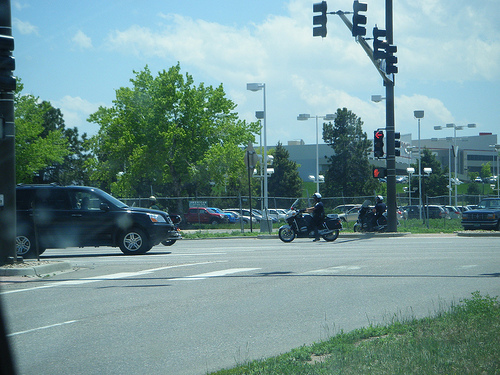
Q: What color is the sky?
A: Blue.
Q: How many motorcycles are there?
A: Two.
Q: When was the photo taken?
A: During the day.